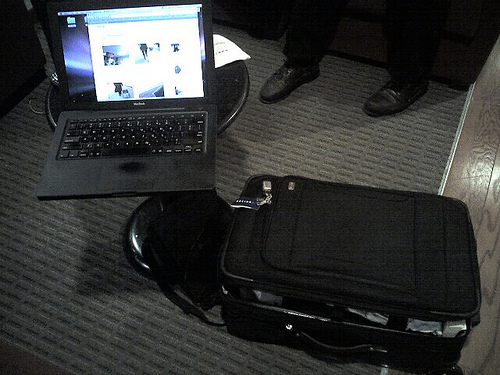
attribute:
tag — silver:
[220, 192, 270, 211]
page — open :
[86, 8, 206, 102]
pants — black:
[278, 0, 433, 81]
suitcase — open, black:
[218, 167, 488, 367]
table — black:
[31, 24, 271, 156]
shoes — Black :
[279, 52, 433, 131]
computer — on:
[26, 2, 234, 187]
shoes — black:
[248, 55, 457, 147]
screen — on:
[46, 4, 213, 109]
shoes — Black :
[253, 56, 498, 191]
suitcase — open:
[211, 139, 488, 359]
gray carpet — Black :
[1, 93, 430, 373]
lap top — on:
[31, 6, 223, 208]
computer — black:
[17, 10, 234, 218]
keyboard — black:
[58, 110, 208, 157]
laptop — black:
[41, 14, 232, 195]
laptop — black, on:
[30, 2, 218, 199]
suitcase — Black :
[213, 153, 483, 365]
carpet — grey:
[0, 21, 465, 373]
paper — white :
[216, 34, 245, 74]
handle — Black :
[283, 323, 389, 365]